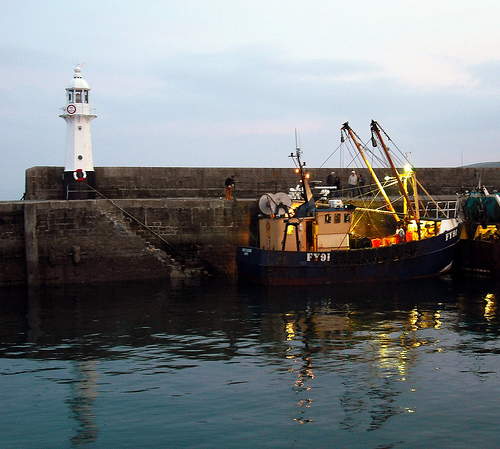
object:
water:
[0, 267, 499, 449]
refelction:
[70, 356, 98, 445]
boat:
[233, 119, 463, 289]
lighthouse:
[58, 64, 101, 199]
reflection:
[277, 309, 355, 361]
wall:
[0, 168, 499, 283]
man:
[223, 175, 236, 202]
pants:
[224, 188, 232, 200]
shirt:
[346, 175, 356, 186]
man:
[347, 170, 360, 198]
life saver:
[73, 168, 86, 182]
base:
[60, 183, 94, 198]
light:
[294, 168, 299, 175]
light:
[304, 171, 311, 180]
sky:
[0, 1, 498, 206]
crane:
[337, 120, 402, 230]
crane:
[366, 119, 423, 230]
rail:
[101, 199, 186, 266]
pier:
[0, 199, 238, 283]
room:
[256, 206, 353, 250]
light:
[402, 162, 413, 178]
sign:
[286, 224, 296, 236]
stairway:
[93, 199, 211, 285]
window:
[77, 155, 82, 160]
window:
[77, 126, 82, 131]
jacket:
[223, 176, 238, 188]